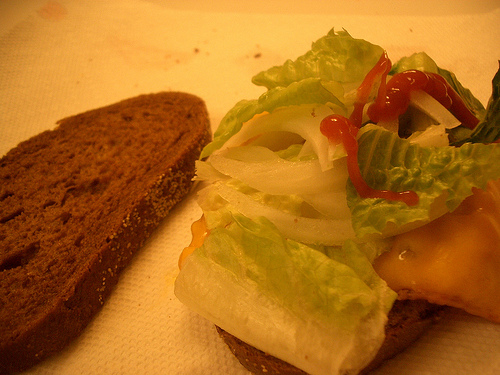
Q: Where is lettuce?
A: On brown bread.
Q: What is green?
A: Lettuce.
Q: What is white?
A: Napkin.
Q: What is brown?
A: Bread.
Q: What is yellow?
A: Cheese.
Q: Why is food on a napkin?
A: To be eaten.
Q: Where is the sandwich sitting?
A: On a paper towel.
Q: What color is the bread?
A: Brown.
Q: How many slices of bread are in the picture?
A: 2.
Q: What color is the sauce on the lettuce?
A: Red.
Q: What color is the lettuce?
A: Green.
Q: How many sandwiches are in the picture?
A: 1.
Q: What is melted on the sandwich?
A: Cheese.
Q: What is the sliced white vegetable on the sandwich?
A: Onion.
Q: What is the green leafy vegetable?
A: Lettuce.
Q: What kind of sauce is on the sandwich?
A: Ketchup.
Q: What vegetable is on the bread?
A: Lettuce.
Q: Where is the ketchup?
A: On the lettuce.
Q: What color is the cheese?
A: Yellow.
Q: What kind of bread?
A: Rye.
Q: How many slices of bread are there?
A: Two.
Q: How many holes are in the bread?
A: Two.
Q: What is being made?
A: Sandwich.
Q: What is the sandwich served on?
A: Towel.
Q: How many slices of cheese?
A: One.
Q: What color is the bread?
A: Brown.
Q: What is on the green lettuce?
A: Ketchup.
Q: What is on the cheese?
A: Ketchup and lettuce.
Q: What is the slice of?
A: Bread.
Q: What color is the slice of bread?
A: Brown.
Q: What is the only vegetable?
A: The tomato.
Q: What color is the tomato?
A: Red.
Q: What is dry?
A: The bread.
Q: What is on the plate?
A: A sandwich.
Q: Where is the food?
A: On the plate.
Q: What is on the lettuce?
A: Ketchup.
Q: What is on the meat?
A: Lettuce.